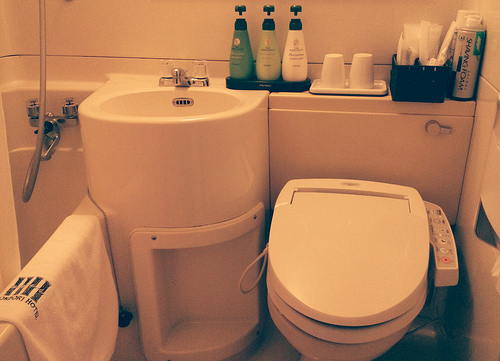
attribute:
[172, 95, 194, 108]
drain — silver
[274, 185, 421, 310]
toilet — white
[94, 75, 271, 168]
sink — white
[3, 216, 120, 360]
bathmat — white, cloth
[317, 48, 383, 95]
cups — white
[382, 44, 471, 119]
box — plastic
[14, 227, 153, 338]
towel — white 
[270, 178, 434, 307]
lid — closed 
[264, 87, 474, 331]
toilet — bathroom's 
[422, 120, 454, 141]
knob — flush 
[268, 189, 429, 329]
lid — white, closed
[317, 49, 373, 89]
cups — white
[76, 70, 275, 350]
sink — white, small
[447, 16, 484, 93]
can — white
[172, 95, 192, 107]
drain — small, silver